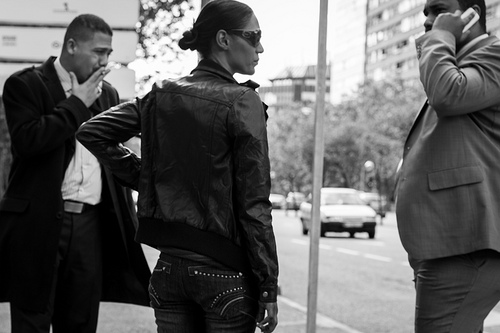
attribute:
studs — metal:
[154, 259, 245, 307]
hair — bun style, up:
[175, 2, 246, 55]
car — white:
[304, 195, 373, 236]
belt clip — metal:
[61, 203, 87, 218]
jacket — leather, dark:
[82, 88, 286, 287]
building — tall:
[358, 7, 499, 168]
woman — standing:
[79, 1, 296, 333]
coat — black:
[4, 62, 150, 308]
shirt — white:
[56, 64, 98, 206]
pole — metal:
[303, 3, 340, 333]